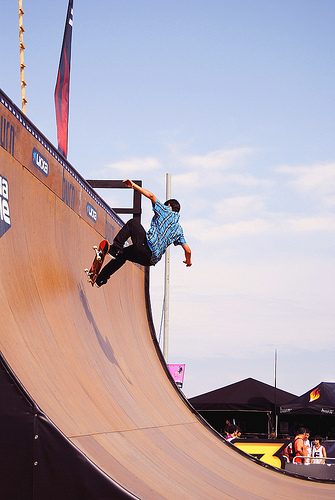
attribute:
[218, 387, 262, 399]
canopy — black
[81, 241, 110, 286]
board — black, brown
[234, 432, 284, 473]
sign — yellow, large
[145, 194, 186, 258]
shirt — blue 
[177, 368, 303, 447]
tent — black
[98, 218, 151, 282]
pants — black 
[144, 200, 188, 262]
shirt — blue 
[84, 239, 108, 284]
skateboard — red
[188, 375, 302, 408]
roof — red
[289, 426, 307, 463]
person — standing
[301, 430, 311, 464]
person — standing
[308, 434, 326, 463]
person — standing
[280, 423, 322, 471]
people — three